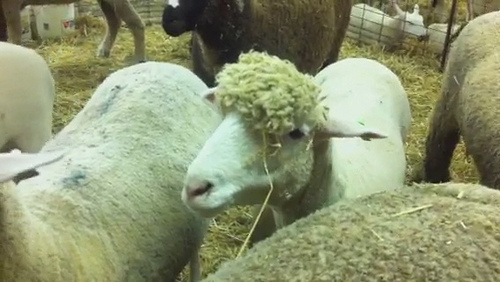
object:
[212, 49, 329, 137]
haircut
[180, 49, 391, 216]
head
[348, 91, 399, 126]
white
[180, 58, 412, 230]
sheep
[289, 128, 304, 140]
eye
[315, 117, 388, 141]
ear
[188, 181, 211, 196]
nose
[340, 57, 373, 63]
end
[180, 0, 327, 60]
black and brown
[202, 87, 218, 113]
ear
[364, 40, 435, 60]
grass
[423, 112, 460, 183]
back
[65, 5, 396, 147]
pen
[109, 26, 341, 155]
by side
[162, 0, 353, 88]
animal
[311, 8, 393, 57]
rear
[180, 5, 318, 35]
unsheared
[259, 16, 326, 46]
brown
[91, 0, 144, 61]
bottom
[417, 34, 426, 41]
metal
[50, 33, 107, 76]
hay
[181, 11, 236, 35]
black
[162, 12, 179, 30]
black nose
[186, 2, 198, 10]
black eyes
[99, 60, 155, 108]
dirt back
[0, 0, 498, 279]
ground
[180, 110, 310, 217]
sheeps face